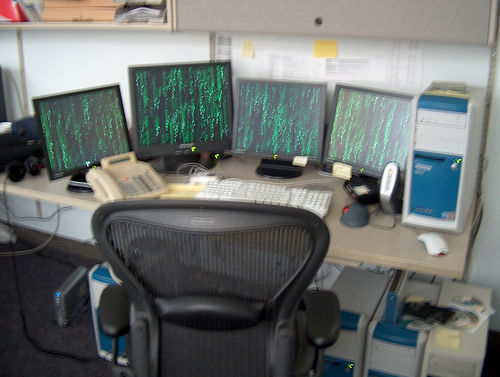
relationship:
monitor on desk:
[91, 48, 243, 151] [242, 74, 323, 160]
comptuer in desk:
[91, 48, 243, 151] [242, 74, 323, 160]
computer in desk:
[91, 48, 243, 151] [242, 74, 323, 160]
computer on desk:
[99, 60, 249, 236] [242, 74, 323, 160]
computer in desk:
[99, 60, 249, 236] [242, 74, 323, 160]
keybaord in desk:
[182, 166, 332, 220] [242, 74, 323, 160]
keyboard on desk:
[182, 166, 332, 220] [183, 172, 378, 240]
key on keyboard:
[276, 179, 337, 223] [182, 166, 332, 220]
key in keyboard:
[276, 179, 337, 223] [182, 166, 332, 220]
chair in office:
[91, 202, 328, 322] [77, 147, 368, 271]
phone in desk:
[74, 142, 180, 217] [79, 132, 161, 190]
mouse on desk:
[324, 182, 374, 237] [183, 172, 378, 240]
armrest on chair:
[77, 275, 139, 340] [303, 300, 351, 350]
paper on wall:
[294, 36, 354, 72] [222, 35, 264, 63]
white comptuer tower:
[205, 38, 237, 62] [145, 41, 178, 61]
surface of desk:
[160, 159, 456, 260] [10, 148, 427, 247]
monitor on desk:
[91, 48, 243, 151] [223, 67, 363, 182]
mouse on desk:
[324, 182, 374, 237] [337, 187, 386, 238]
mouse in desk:
[324, 182, 374, 237] [337, 187, 386, 238]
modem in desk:
[353, 160, 406, 203] [350, 153, 421, 221]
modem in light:
[353, 160, 406, 203] [366, 174, 402, 215]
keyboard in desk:
[182, 166, 332, 220] [162, 150, 359, 233]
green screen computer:
[91, 48, 243, 151] [99, 60, 249, 236]